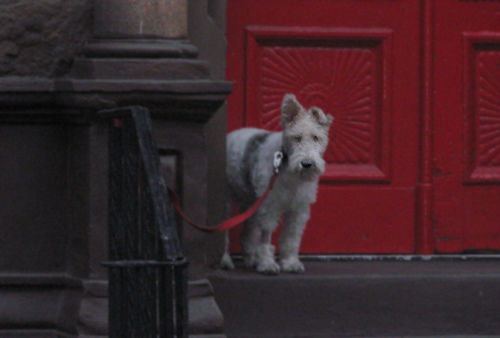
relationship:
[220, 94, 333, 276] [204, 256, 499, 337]
dog standing on stoop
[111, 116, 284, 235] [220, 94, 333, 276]
leash on dog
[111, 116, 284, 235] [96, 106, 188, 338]
leash attached to handrail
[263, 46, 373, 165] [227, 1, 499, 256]
design carved in doors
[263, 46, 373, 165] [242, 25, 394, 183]
design with frame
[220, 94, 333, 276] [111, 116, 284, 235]
dog with leash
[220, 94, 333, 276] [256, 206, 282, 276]
dog has leg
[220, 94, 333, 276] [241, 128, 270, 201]
dog has strip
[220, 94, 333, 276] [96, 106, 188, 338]
dog chained to handrail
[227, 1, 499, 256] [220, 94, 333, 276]
doors behind dog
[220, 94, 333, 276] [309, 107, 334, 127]
dog has ear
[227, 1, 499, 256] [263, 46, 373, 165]
doors have design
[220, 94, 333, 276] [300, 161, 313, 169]
dog has nose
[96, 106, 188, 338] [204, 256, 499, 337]
handrail for stoop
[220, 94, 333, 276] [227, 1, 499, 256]
dog standing by doors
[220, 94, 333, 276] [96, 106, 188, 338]
dog leashed to handrail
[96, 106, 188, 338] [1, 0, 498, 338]
handrail on building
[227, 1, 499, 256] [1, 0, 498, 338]
doors are on building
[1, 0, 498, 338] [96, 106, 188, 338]
building has handrail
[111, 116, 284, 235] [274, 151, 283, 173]
leash has clasp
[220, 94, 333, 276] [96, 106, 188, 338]
dog tied to handrail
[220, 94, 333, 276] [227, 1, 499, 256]
dog in front of doors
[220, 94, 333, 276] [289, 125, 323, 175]
dog has face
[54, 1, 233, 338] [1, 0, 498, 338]
post on building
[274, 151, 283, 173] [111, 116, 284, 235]
clasp on leash